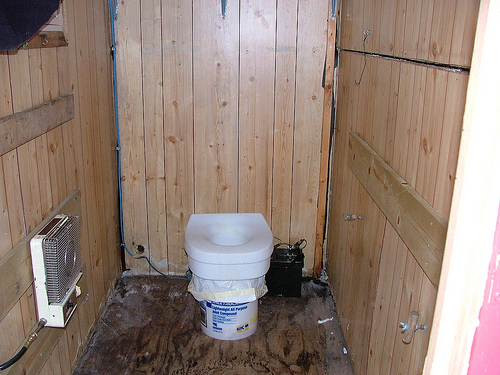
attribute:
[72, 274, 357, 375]
floor — plywood, stained, molded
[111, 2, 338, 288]
wall — wood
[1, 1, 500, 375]
outhouse — pink, wooden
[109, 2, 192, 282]
cord — blue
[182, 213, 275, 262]
seat — plastic, white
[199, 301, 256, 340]
bucket — white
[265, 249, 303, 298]
battery — black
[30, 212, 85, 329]
heater — silver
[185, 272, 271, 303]
bag — plastic, white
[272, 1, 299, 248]
panel — wooden, cheap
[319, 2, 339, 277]
wire — running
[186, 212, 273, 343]
toilet — questionable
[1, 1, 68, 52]
window — wooden